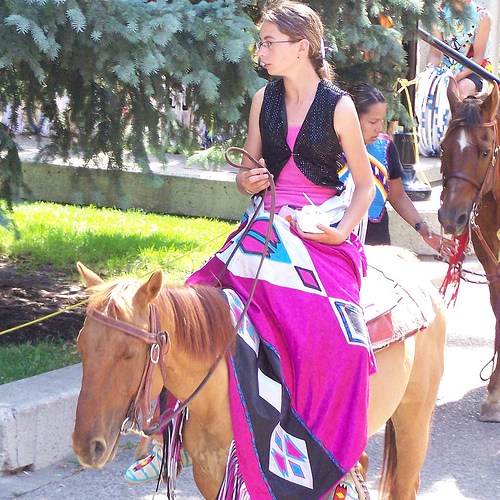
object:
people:
[120, 0, 377, 486]